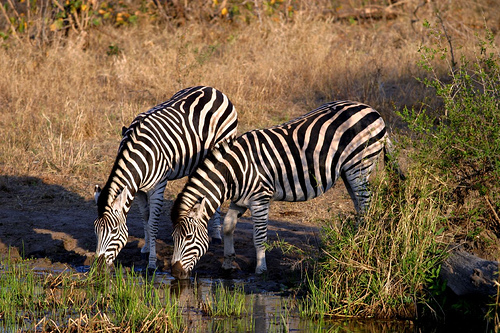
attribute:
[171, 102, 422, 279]
zebra — drinking, black, white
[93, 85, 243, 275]
zebra — drinking, black, white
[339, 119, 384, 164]
stripe — rust colored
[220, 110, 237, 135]
stripe — rust colored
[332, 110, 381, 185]
stripe — black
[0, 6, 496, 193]
grass — brown, dry, high, dried out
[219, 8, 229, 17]
leaf — yellow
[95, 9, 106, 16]
leaf — yellow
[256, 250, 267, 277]
ankle — white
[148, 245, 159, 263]
ankle — white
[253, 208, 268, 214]
stripe — small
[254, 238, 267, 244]
stripe — thin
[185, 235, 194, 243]
eye — black, ringed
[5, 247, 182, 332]
grass — green, high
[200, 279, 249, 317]
grass — green, high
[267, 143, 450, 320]
grass — tall, high, swamp grass, in a clump, green, marshy, dry, fresh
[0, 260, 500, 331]
water — muddy, shallow, standing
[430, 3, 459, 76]
branch — leafless, growing, thin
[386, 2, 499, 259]
bush — sparse, green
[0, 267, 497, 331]
creek — small, boggy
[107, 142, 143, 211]
neck — down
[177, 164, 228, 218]
neck — down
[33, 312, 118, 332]
stalks — brown, dried out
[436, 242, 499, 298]
tree trunk — dry, dead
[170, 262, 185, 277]
nose — brown